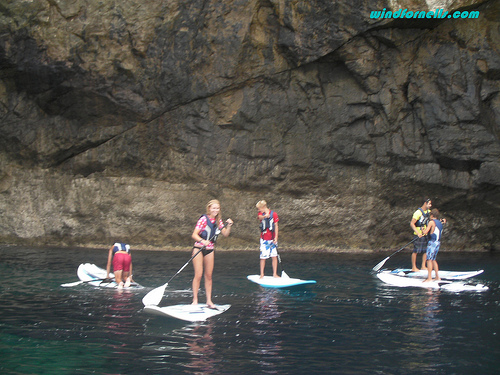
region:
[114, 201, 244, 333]
woman standing on a paddle board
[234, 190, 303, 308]
man standing on a board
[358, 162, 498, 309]
two people on boards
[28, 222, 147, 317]
a person kneeling on a board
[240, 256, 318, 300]
a white board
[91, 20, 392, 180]
a rocky cliff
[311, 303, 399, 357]
calm blue water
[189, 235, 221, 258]
black swim suit bottoms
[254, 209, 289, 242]
a red shirt on a man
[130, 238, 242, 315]
a paddle oar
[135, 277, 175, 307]
The row is white.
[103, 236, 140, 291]
Person sitting on their knees.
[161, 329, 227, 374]
Reflection in the water.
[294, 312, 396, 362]
The water is grey.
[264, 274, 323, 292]
Side of the surfboard is blue.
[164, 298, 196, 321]
The surfboard is white.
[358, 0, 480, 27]
Website at the top.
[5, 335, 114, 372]
Small part of the water is green.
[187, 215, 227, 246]
Girl is wearing a life vest.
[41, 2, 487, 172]
Crack in the cliff.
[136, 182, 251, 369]
a woman standing on a board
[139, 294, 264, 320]
a white board in the water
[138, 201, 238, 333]
a white paddle in the air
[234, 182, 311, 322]
a man standing on a board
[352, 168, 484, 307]
two people standing on boards in the water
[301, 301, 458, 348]
calm blue water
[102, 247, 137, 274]
red shorts on a person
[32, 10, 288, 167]
brown rock wall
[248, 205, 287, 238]
a life jacket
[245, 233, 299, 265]
white swim shorts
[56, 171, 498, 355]
five people in water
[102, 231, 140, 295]
butt of man in pink shorts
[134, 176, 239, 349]
girl paddling in water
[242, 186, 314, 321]
boy standing on surf board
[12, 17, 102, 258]
rock cliff next to water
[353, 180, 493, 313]
two people paddling in water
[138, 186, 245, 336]
girl paddling standing up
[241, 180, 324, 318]
boy in water with safety vest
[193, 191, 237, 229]
smiling face of blond haired girl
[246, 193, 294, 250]
blond haired boy in pink shirt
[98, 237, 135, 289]
person on paddle board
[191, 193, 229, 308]
person on paddle board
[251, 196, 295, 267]
person on paddle board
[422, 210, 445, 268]
person on paddle board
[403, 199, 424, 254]
person on paddle board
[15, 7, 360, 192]
tan and black rock wall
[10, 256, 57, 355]
green and black water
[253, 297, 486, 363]
green and black water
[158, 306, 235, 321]
paddle board used by woman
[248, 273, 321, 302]
paddle board used by man